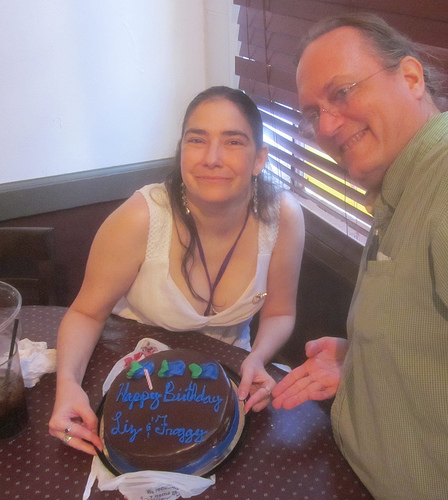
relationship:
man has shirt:
[265, 13, 446, 482] [331, 107, 447, 498]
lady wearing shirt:
[51, 84, 306, 457] [111, 194, 288, 333]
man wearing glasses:
[265, 13, 446, 482] [300, 89, 373, 137]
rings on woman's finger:
[45, 415, 80, 464] [47, 426, 97, 456]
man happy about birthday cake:
[265, 13, 446, 482] [102, 349, 240, 477]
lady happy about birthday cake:
[47, 85, 305, 457] [102, 349, 240, 477]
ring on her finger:
[63, 432, 72, 443] [50, 428, 97, 456]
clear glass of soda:
[0, 275, 38, 433] [0, 375, 38, 437]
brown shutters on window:
[228, 1, 326, 110] [254, 99, 369, 239]